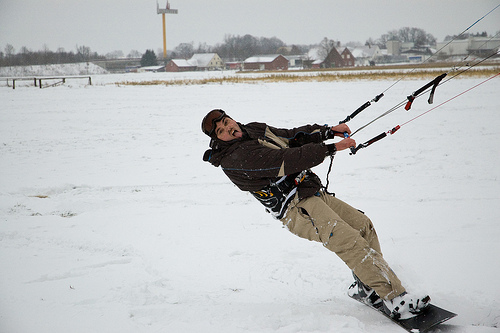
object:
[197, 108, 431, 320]
man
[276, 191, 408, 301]
pants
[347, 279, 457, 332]
board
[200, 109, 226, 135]
eyewear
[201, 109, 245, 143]
head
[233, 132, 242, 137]
tongue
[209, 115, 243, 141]
face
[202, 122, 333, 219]
coat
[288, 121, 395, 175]
harness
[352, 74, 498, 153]
wire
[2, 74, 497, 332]
field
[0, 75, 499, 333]
snow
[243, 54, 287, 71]
building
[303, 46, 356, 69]
building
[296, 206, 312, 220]
pocket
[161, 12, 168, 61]
pole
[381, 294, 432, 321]
feet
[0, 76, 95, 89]
fence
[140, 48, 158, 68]
tree